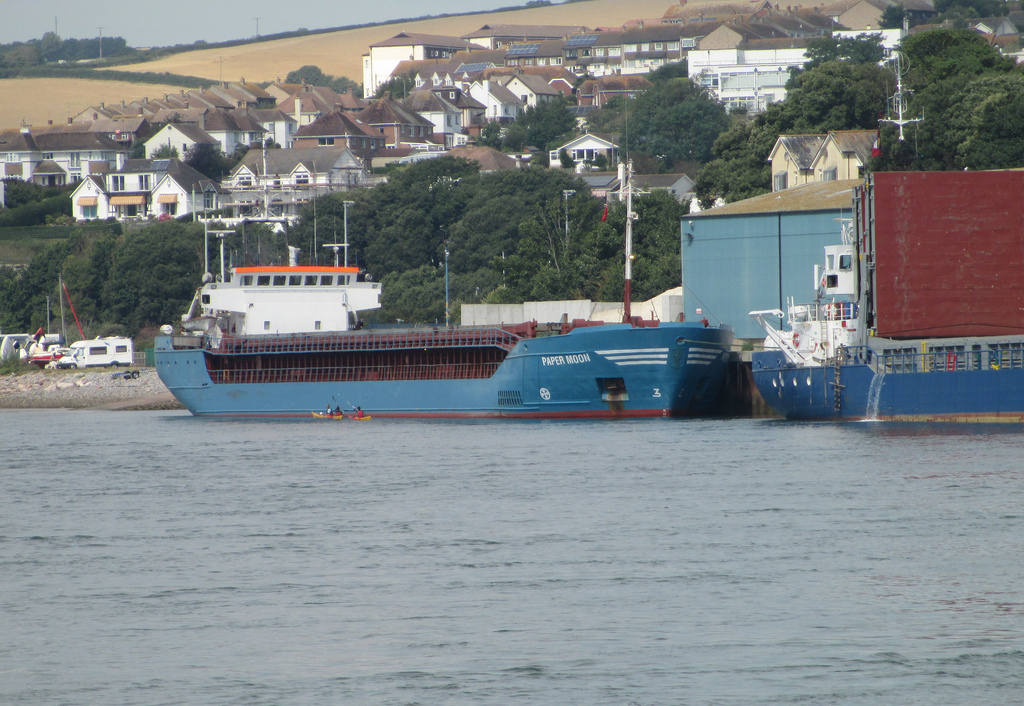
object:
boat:
[151, 314, 734, 420]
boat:
[747, 297, 1024, 423]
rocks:
[0, 366, 175, 409]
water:
[0, 405, 1024, 706]